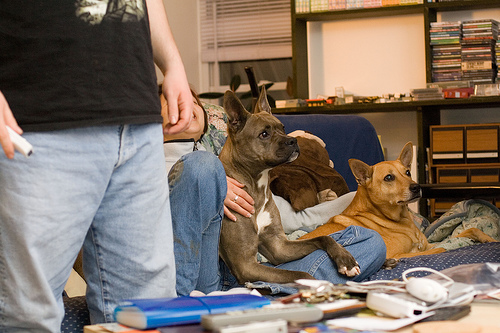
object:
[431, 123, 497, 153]
cd holder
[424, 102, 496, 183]
desk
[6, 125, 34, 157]
controller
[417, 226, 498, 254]
legs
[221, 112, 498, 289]
couch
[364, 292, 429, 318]
wii remote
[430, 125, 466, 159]
wooden boxes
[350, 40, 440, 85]
wall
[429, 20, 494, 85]
cd cases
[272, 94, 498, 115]
shelf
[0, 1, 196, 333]
man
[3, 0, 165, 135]
t-shirt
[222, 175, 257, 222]
hand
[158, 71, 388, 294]
person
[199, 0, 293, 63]
blinds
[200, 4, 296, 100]
window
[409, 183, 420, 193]
nose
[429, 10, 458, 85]
stack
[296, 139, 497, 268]
dog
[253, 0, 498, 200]
desk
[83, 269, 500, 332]
table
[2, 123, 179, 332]
blue jeans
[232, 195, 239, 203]
ring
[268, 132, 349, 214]
dog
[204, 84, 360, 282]
dog